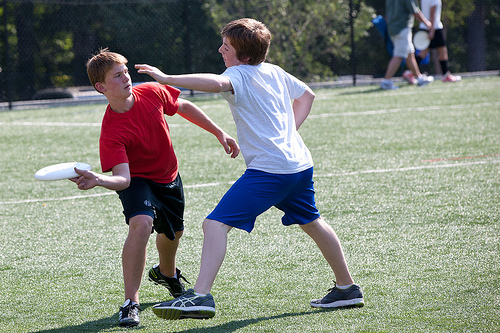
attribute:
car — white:
[38, 85, 105, 98]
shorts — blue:
[219, 164, 324, 231]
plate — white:
[40, 143, 94, 188]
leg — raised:
[167, 162, 263, 303]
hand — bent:
[74, 172, 93, 189]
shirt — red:
[117, 85, 188, 186]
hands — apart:
[67, 132, 241, 202]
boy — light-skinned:
[51, 47, 200, 324]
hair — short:
[79, 40, 118, 79]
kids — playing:
[52, 38, 359, 328]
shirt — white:
[229, 63, 325, 190]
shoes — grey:
[156, 280, 371, 327]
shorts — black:
[112, 165, 196, 248]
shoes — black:
[112, 251, 185, 329]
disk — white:
[35, 156, 97, 178]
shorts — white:
[387, 26, 415, 57]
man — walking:
[420, 4, 461, 91]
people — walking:
[369, 3, 460, 72]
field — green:
[332, 100, 482, 328]